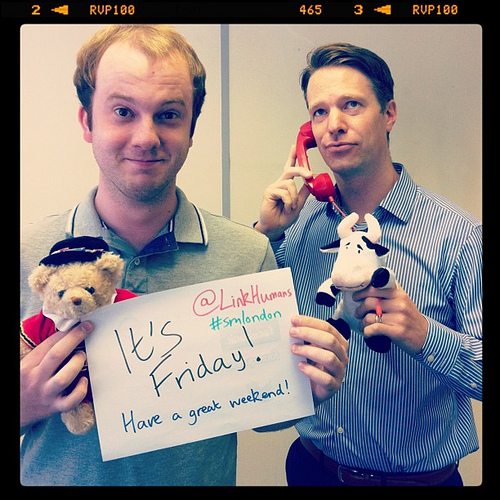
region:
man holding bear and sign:
[47, 76, 212, 416]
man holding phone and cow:
[275, 70, 458, 457]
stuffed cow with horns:
[307, 213, 404, 356]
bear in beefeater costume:
[9, 225, 136, 422]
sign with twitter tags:
[175, 287, 312, 350]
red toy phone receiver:
[279, 96, 334, 216]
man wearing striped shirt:
[278, 64, 463, 339]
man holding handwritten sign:
[92, 309, 318, 456]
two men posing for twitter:
[78, 36, 468, 396]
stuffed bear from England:
[27, 222, 178, 437]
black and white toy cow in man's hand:
[312, 213, 399, 348]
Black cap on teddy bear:
[32, 229, 116, 265]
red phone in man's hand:
[287, 119, 341, 206]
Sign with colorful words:
[87, 285, 294, 442]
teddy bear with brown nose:
[28, 239, 119, 308]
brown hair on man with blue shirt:
[297, 42, 405, 97]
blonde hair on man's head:
[71, 32, 212, 64]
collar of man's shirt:
[140, 212, 216, 262]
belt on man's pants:
[300, 444, 468, 485]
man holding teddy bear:
[29, 229, 126, 435]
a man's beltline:
[280, 425, 480, 485]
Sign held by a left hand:
[115, 270, 345, 441]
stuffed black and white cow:
[325, 205, 400, 350]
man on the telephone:
[285, 80, 350, 210]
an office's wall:
[211, 25, 276, 175]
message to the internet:
[110, 286, 295, 426]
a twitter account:
[191, 271, 301, 331]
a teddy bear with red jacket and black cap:
[25, 226, 132, 322]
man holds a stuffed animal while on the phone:
[291, 35, 471, 315]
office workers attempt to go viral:
[60, 25, 415, 455]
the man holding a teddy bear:
[36, 30, 286, 497]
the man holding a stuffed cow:
[267, 47, 478, 482]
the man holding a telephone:
[232, 54, 467, 479]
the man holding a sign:
[43, 50, 314, 477]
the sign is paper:
[38, 262, 334, 449]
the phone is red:
[286, 114, 346, 217]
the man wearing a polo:
[40, 182, 295, 488]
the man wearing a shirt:
[274, 152, 475, 492]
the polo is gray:
[43, 207, 294, 477]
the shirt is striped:
[267, 180, 465, 480]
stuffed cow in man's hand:
[302, 213, 400, 346]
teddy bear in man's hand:
[1, 229, 138, 459]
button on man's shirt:
[328, 417, 353, 442]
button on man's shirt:
[423, 353, 438, 368]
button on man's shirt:
[465, 380, 481, 392]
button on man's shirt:
[339, 376, 349, 394]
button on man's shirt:
[129, 259, 141, 269]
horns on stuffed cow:
[323, 205, 390, 265]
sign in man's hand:
[98, 293, 315, 450]